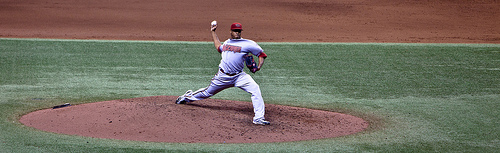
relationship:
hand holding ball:
[209, 20, 225, 34] [209, 19, 222, 28]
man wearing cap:
[197, 22, 265, 125] [228, 21, 245, 31]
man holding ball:
[197, 15, 264, 117] [209, 19, 222, 28]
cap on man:
[228, 21, 245, 31] [197, 15, 264, 117]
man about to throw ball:
[197, 15, 264, 117] [209, 19, 222, 28]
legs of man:
[187, 65, 273, 111] [197, 15, 264, 117]